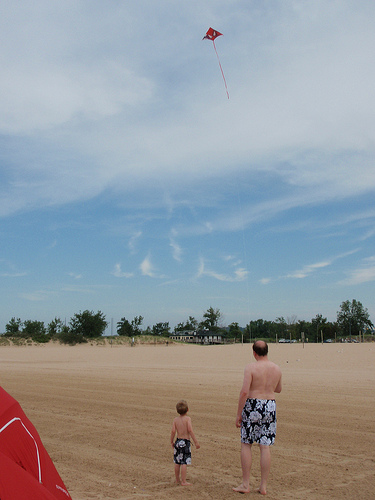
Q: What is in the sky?
A: A kite.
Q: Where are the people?
A: On a beach.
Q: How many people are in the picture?
A: Two.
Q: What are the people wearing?
A: Swimming trunks.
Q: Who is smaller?
A: The boy.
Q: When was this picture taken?
A: During the day.